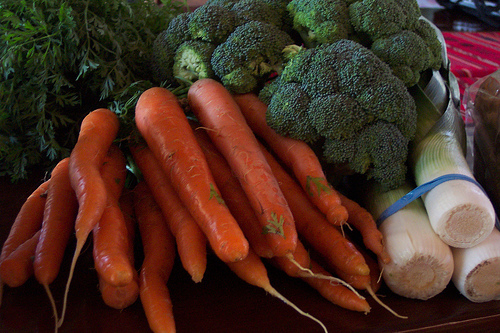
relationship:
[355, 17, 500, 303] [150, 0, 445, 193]
leeks next to broccoli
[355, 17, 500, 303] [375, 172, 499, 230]
leeks tied by rubberband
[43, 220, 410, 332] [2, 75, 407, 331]
roots at ends of carrots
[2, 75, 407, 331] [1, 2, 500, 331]
carrots on table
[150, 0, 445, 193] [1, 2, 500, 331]
broccoli on table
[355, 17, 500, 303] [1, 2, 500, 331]
leeks on table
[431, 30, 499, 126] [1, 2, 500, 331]
cloth on table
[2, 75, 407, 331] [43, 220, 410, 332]
carrots have roots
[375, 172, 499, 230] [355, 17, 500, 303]
rubberband on leeks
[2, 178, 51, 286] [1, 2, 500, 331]
carrot on table